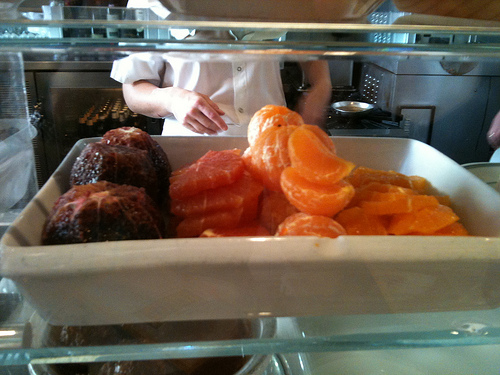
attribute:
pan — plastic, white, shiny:
[13, 237, 499, 319]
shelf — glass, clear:
[32, 321, 499, 361]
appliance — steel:
[394, 63, 491, 144]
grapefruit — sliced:
[172, 150, 264, 234]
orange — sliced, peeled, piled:
[370, 167, 456, 235]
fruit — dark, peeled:
[46, 180, 160, 239]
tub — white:
[0, 120, 35, 204]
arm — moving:
[128, 80, 166, 118]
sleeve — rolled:
[119, 59, 154, 79]